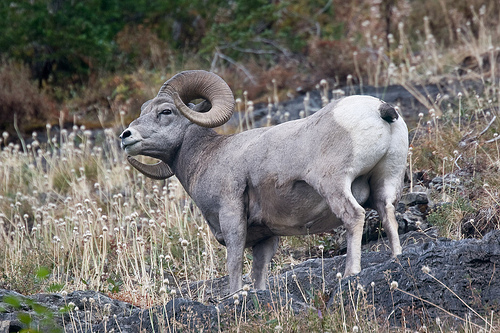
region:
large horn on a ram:
[157, 60, 248, 132]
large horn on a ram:
[122, 148, 183, 185]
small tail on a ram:
[375, 95, 415, 130]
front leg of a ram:
[207, 176, 264, 305]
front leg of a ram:
[237, 213, 288, 321]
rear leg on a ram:
[316, 162, 383, 294]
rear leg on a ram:
[370, 161, 417, 270]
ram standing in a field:
[110, 37, 439, 306]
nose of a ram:
[117, 125, 136, 146]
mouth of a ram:
[116, 137, 148, 157]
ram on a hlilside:
[98, 48, 435, 304]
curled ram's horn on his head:
[147, 59, 252, 131]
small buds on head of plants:
[14, 201, 210, 283]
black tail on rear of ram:
[366, 96, 416, 125]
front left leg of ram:
[200, 180, 258, 318]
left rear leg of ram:
[307, 161, 373, 284]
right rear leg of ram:
[370, 175, 405, 262]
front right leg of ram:
[247, 241, 274, 298]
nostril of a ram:
[115, 124, 136, 144]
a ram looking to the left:
[68, 40, 459, 292]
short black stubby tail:
[373, 93, 405, 135]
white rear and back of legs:
[324, 78, 418, 253]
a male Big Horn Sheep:
[116, 63, 418, 275]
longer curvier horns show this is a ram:
[111, 68, 235, 180]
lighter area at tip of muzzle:
[101, 120, 153, 163]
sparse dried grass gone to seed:
[0, 111, 122, 299]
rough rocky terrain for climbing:
[31, 192, 498, 332]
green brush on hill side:
[5, 1, 312, 72]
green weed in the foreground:
[1, 249, 71, 331]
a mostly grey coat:
[146, 82, 350, 282]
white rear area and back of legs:
[332, 86, 417, 250]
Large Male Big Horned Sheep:
[115, 62, 410, 294]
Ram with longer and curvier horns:
[110, 60, 225, 186]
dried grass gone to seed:
[1, 126, 121, 267]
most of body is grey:
[115, 71, 347, 241]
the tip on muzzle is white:
[100, 110, 172, 170]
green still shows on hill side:
[11, 0, 298, 55]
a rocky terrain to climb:
[66, 225, 496, 330]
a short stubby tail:
[362, 87, 417, 135]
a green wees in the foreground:
[0, 262, 80, 332]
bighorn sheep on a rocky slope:
[31, 14, 459, 314]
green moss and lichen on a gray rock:
[4, 288, 76, 328]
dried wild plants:
[4, 203, 151, 295]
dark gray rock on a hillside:
[295, 263, 431, 330]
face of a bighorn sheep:
[113, 93, 188, 156]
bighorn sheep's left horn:
[159, 61, 249, 128]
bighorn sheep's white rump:
[331, 82, 413, 199]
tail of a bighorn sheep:
[375, 99, 400, 124]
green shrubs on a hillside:
[9, 4, 299, 69]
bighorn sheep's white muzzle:
[116, 126, 151, 155]